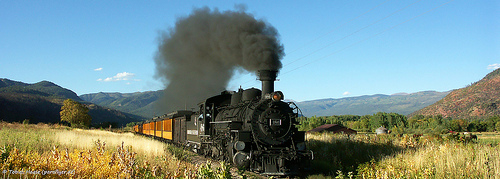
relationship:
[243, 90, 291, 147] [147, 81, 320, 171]
front view of train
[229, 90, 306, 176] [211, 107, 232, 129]
front view of train black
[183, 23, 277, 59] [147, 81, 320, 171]
smoke coming from train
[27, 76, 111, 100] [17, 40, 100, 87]
mountains in background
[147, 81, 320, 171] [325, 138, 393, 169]
train casting a shadow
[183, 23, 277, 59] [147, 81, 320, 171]
smoke coming out of train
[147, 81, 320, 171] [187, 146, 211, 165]
train on tracks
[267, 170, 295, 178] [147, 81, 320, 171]
track for train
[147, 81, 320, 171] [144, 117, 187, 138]
train has cars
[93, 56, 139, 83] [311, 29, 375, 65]
clouds in sky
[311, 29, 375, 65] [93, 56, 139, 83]
sky has some clouds